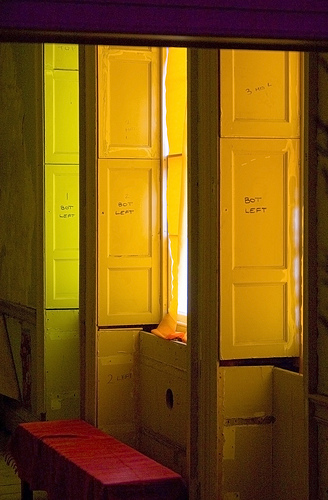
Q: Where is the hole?
A: In the wall.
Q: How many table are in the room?
A: 1.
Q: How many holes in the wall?
A: 1.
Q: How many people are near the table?
A: 0.